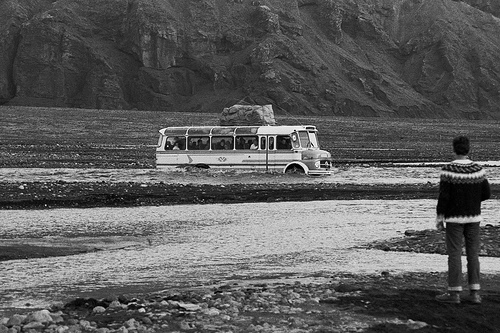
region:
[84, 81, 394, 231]
Th bus is driving through water.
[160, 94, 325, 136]
The bus is carrying cargo.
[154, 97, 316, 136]
The cargo is on the bus' roof.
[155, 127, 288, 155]
People are in the bus.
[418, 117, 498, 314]
A man watches the bus.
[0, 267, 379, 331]
The ground is very rocky.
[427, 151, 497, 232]
The man wears a sweater.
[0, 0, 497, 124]
A hill is in the background.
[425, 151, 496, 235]
The man's sweater is patterned.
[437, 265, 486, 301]
The man's pants are rolled up.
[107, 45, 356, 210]
a bus in the water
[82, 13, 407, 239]
a bus submerged in the water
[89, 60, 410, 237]
a bus with people on it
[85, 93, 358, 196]
a bus with people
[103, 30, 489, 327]
a guy looking at the bus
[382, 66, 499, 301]
a guy wearing boots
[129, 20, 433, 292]
a bus trapped in the water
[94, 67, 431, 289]
a bus in the water with people on it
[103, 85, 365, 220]
an old bus in the water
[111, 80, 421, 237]
an old bus with people on it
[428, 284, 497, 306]
Person wearing boots.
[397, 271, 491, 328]
Person standing in dirt.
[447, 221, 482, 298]
Person wearing dark pants.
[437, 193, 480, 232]
Person wearing big sweater.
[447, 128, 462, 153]
Person has short hair.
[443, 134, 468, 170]
Person has dark hair.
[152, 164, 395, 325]
Rocks on ground near water.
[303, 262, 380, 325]
Dirt near the rocks.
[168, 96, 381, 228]
Bus driving thru the water.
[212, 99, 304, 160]
Large object on top of bus.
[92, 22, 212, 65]
rock in the background.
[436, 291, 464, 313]
shoe on man's foot.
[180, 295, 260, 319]
rocks on the shore.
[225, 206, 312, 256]
water near the shore.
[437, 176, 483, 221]
sweater on man's torso.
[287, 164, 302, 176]
bus tire in the water.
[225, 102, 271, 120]
luggage on top of bus.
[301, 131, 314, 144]
windshield of the bus.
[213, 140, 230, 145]
window on side of bus.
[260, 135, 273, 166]
door on side of bus.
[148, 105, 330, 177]
this is a bus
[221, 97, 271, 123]
luggage are on the bus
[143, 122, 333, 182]
the bus is in water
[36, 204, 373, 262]
this is water in front of the man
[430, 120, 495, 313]
this is a man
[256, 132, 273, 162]
the door is closed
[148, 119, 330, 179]
the bus is old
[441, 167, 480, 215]
the man is wearing sweater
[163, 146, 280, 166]
the bus is white in color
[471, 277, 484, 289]
the trousers are folded